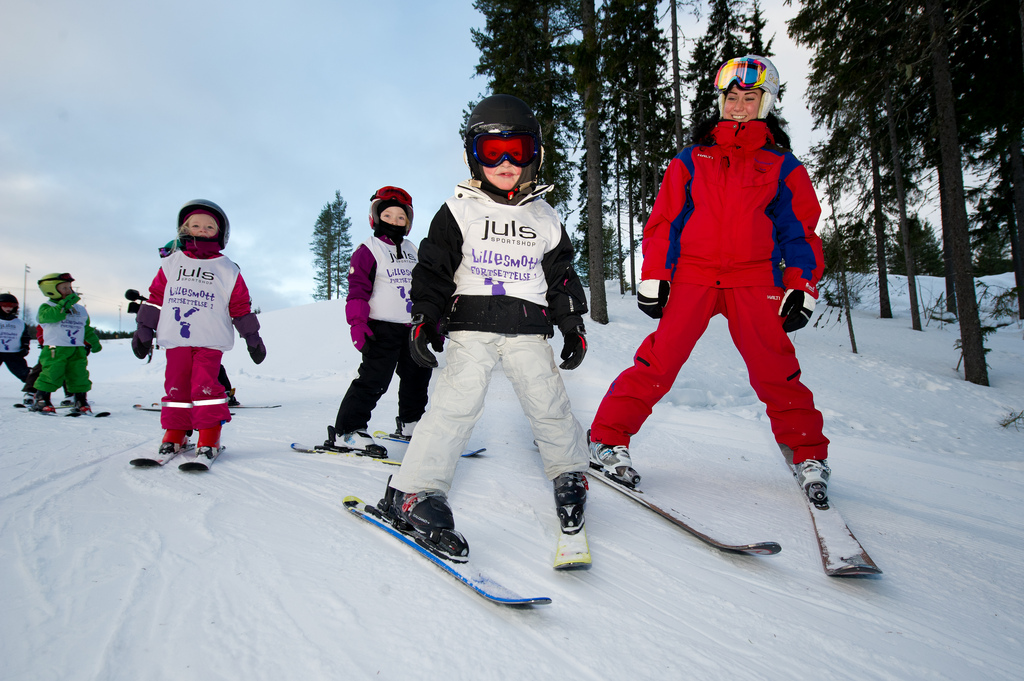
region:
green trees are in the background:
[883, 26, 1000, 377]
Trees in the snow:
[822, 6, 1022, 373]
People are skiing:
[0, 58, 841, 562]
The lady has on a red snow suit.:
[601, 55, 811, 457]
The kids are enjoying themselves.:
[125, 95, 585, 558]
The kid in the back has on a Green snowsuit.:
[27, 273, 103, 407]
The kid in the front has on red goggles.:
[477, 117, 536, 171]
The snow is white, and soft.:
[27, 498, 329, 666]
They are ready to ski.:
[11, 63, 888, 463]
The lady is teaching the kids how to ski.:
[584, 51, 899, 589]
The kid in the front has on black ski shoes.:
[379, 467, 626, 554]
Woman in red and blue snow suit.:
[603, 62, 876, 604]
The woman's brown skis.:
[631, 463, 907, 580]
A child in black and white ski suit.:
[369, 108, 597, 606]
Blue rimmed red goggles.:
[454, 128, 566, 176]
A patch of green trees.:
[436, 1, 773, 65]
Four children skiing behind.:
[2, 197, 423, 485]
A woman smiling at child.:
[691, 49, 816, 122]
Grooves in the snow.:
[514, 618, 947, 679]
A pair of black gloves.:
[113, 329, 282, 371]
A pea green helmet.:
[22, 271, 111, 300]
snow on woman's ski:
[815, 510, 882, 583]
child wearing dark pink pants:
[161, 348, 229, 451]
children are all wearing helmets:
[0, 102, 558, 315]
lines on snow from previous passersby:
[580, 580, 942, 661]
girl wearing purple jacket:
[343, 250, 373, 327]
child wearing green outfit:
[34, 270, 88, 416]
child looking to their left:
[34, 269, 92, 323]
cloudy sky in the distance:
[16, 156, 412, 236]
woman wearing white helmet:
[759, 65, 788, 110]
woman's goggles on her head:
[705, 55, 772, 98]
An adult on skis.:
[620, 44, 858, 552]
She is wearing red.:
[646, 115, 835, 467]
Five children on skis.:
[0, 99, 571, 463]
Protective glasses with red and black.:
[467, 126, 543, 181]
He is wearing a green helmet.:
[32, 269, 90, 313]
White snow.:
[84, 485, 330, 662]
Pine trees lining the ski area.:
[848, 100, 1017, 395]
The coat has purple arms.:
[335, 243, 398, 364]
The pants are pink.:
[150, 333, 257, 465]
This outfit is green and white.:
[26, 299, 116, 412]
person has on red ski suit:
[637, 124, 847, 505]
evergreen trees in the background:
[782, 1, 1020, 391]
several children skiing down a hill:
[25, 101, 576, 639]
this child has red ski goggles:
[455, 123, 560, 168]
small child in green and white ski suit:
[30, 278, 103, 431]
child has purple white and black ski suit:
[323, 180, 432, 436]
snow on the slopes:
[30, 475, 436, 675]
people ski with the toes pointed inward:
[577, 440, 923, 605]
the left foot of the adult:
[801, 456, 847, 527]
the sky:
[8, 10, 465, 153]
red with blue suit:
[632, 118, 841, 551]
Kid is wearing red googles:
[423, 81, 557, 230]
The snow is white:
[60, 469, 361, 622]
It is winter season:
[32, 46, 911, 600]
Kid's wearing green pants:
[32, 263, 102, 415]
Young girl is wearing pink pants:
[148, 337, 259, 489]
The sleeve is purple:
[328, 238, 398, 366]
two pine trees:
[291, 155, 374, 312]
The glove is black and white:
[776, 288, 814, 350]